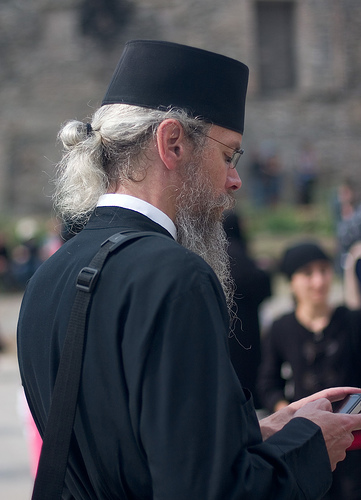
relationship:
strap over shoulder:
[3, 231, 140, 497] [137, 246, 220, 284]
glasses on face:
[186, 133, 261, 168] [191, 124, 242, 227]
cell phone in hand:
[334, 393, 361, 414] [292, 397, 359, 470]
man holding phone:
[14, 38, 361, 500] [313, 369, 359, 437]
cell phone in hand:
[331, 390, 360, 425] [294, 412, 361, 471]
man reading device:
[14, 38, 361, 500] [333, 391, 359, 421]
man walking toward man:
[14, 38, 361, 500] [260, 242, 359, 387]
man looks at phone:
[14, 38, 361, 500] [325, 386, 360, 423]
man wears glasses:
[16, 28, 276, 382] [193, 124, 253, 169]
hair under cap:
[51, 103, 206, 228] [101, 41, 249, 134]